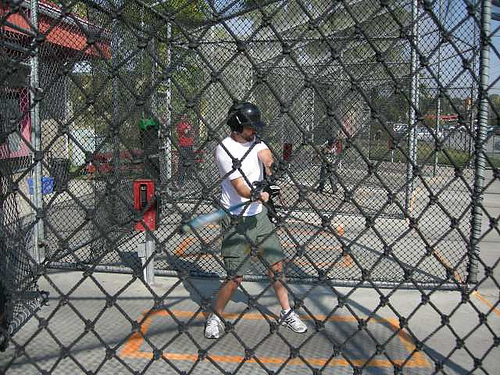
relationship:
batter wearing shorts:
[201, 94, 306, 341] [217, 211, 285, 281]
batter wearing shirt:
[201, 99, 306, 341] [209, 139, 293, 236]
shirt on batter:
[209, 139, 280, 221] [180, 91, 319, 352]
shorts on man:
[191, 203, 336, 299] [192, 97, 352, 341]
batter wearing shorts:
[201, 99, 306, 341] [209, 197, 289, 273]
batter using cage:
[201, 99, 306, 341] [4, 7, 482, 347]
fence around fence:
[1, 10, 498, 367] [0, 0, 499, 374]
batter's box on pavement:
[119, 313, 429, 374] [3, 156, 496, 372]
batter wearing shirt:
[201, 99, 306, 341] [174, 122, 196, 148]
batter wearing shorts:
[201, 99, 306, 341] [218, 214, 285, 269]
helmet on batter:
[229, 98, 274, 135] [204, 103, 302, 330]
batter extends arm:
[201, 99, 306, 341] [260, 145, 276, 177]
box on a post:
[131, 172, 156, 234] [142, 232, 155, 285]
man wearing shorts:
[174, 114, 201, 188] [217, 204, 285, 279]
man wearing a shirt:
[174, 114, 201, 188] [177, 117, 196, 146]